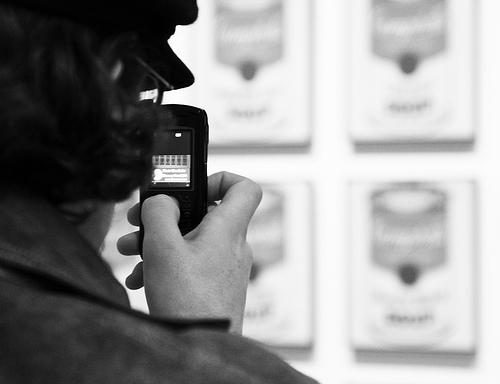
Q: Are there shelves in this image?
A: No, there are no shelves.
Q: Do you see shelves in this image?
A: No, there are no shelves.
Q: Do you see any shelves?
A: No, there are no shelves.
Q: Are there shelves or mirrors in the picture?
A: No, there are no shelves or mirrors.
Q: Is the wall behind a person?
A: Yes, the wall is behind a person.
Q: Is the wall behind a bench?
A: No, the wall is behind a person.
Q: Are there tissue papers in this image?
A: No, there are no tissue papers.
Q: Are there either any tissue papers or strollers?
A: No, there are no tissue papers or strollers.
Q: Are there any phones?
A: Yes, there is a phone.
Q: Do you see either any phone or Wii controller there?
A: Yes, there is a phone.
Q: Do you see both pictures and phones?
A: Yes, there are both a phone and a picture.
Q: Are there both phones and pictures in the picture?
A: Yes, there are both a phone and a picture.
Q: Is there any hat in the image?
A: Yes, there is a hat.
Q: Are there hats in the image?
A: Yes, there is a hat.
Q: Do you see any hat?
A: Yes, there is a hat.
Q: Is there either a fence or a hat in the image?
A: Yes, there is a hat.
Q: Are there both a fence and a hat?
A: No, there is a hat but no fences.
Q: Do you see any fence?
A: No, there are no fences.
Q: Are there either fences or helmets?
A: No, there are no fences or helmets.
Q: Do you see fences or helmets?
A: No, there are no fences or helmets.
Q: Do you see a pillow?
A: No, there are no pillows.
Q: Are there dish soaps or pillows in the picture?
A: No, there are no pillows or dish soaps.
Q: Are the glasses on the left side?
A: Yes, the glasses are on the left of the image.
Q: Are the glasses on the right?
A: No, the glasses are on the left of the image.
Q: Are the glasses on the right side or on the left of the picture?
A: The glasses are on the left of the image.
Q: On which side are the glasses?
A: The glasses are on the left of the image.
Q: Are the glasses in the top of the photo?
A: Yes, the glasses are in the top of the image.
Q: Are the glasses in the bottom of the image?
A: No, the glasses are in the top of the image.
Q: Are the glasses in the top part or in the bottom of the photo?
A: The glasses are in the top of the image.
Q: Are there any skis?
A: No, there are no skis.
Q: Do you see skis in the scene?
A: No, there are no skis.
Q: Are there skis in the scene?
A: No, there are no skis.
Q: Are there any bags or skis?
A: No, there are no skis or bags.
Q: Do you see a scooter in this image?
A: No, there are no scooters.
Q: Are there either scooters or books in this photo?
A: No, there are no scooters or books.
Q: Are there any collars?
A: Yes, there is a collar.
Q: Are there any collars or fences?
A: Yes, there is a collar.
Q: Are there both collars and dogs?
A: No, there is a collar but no dogs.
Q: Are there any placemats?
A: No, there are no placemats.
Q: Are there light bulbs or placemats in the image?
A: No, there are no placemats or light bulbs.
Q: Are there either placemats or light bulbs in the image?
A: No, there are no placemats or light bulbs.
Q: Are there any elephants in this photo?
A: No, there are no elephants.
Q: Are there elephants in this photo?
A: No, there are no elephants.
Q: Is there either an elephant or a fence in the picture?
A: No, there are no elephants or fences.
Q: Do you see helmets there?
A: No, there are no helmets.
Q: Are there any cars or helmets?
A: No, there are no helmets or cars.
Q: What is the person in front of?
A: The person is in front of the wall.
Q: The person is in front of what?
A: The person is in front of the wall.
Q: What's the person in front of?
A: The person is in front of the wall.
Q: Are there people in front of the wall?
A: Yes, there is a person in front of the wall.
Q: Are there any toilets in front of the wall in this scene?
A: No, there is a person in front of the wall.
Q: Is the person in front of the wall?
A: Yes, the person is in front of the wall.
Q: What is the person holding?
A: The person is holding the phone.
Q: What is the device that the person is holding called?
A: The device is a phone.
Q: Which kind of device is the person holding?
A: The person is holding the phone.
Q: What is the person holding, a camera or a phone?
A: The person is holding a phone.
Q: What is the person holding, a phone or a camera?
A: The person is holding a phone.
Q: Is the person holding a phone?
A: Yes, the person is holding a phone.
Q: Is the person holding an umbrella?
A: No, the person is holding a phone.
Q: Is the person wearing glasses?
A: Yes, the person is wearing glasses.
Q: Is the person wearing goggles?
A: No, the person is wearing glasses.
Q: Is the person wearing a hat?
A: Yes, the person is wearing a hat.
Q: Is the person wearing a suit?
A: No, the person is wearing a hat.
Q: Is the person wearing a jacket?
A: Yes, the person is wearing a jacket.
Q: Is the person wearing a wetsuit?
A: No, the person is wearing a jacket.